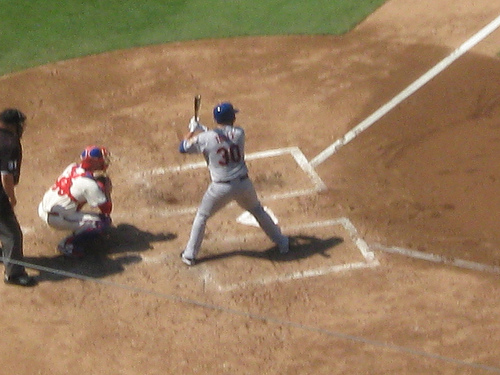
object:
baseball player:
[179, 93, 290, 265]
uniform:
[34, 162, 115, 262]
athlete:
[0, 106, 40, 286]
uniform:
[181, 125, 289, 260]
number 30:
[216, 143, 242, 166]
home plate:
[232, 203, 281, 227]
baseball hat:
[211, 101, 241, 120]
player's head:
[212, 102, 241, 128]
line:
[307, 15, 499, 172]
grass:
[0, 0, 388, 76]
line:
[364, 237, 499, 275]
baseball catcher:
[36, 145, 114, 260]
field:
[1, 0, 499, 374]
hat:
[79, 143, 112, 174]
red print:
[214, 132, 243, 166]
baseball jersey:
[182, 123, 248, 182]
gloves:
[186, 114, 208, 134]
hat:
[212, 102, 239, 123]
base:
[233, 198, 282, 237]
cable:
[0, 256, 499, 374]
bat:
[192, 93, 201, 132]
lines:
[133, 15, 500, 294]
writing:
[216, 133, 236, 145]